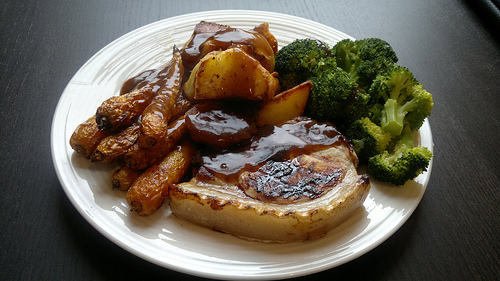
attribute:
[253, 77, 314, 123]
white potato — large